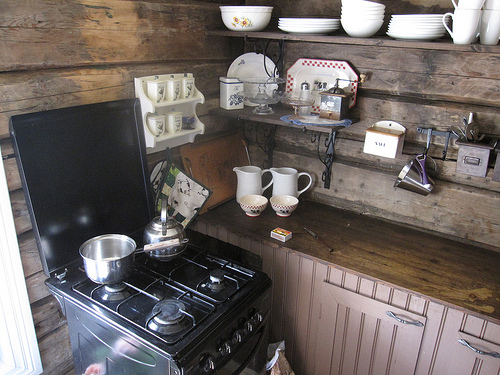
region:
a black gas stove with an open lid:
[6, 97, 278, 372]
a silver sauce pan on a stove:
[76, 233, 188, 286]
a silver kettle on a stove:
[140, 192, 191, 259]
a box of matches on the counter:
[268, 225, 293, 242]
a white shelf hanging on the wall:
[133, 70, 209, 156]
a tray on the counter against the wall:
[174, 131, 256, 214]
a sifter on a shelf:
[321, 73, 367, 122]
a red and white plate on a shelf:
[283, 58, 360, 116]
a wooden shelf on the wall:
[208, 102, 362, 190]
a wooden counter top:
[195, 192, 499, 357]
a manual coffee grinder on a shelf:
[320, 72, 368, 124]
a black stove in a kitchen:
[11, 100, 270, 372]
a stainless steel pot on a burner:
[81, 233, 138, 283]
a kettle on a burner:
[146, 192, 188, 256]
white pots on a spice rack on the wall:
[135, 74, 206, 151]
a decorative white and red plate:
[284, 56, 356, 109]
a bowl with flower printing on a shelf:
[218, 3, 273, 28]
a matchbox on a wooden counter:
[271, 225, 291, 245]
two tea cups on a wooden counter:
[240, 195, 301, 217]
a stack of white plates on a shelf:
[386, 13, 449, 41]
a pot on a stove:
[68, 237, 187, 287]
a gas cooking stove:
[57, 231, 262, 326]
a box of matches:
[254, 220, 294, 254]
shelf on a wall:
[224, 71, 373, 130]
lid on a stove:
[3, 89, 150, 274]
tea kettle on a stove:
[139, 196, 193, 266]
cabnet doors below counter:
[309, 274, 457, 371]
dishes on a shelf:
[209, 7, 499, 47]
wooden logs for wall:
[14, 2, 206, 104]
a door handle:
[383, 308, 437, 332]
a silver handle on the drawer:
[380, 303, 421, 330]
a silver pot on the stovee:
[80, 231, 135, 293]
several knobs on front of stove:
[197, 316, 246, 369]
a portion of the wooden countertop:
[381, 215, 492, 286]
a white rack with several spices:
[137, 77, 214, 141]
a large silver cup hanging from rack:
[398, 122, 436, 208]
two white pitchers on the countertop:
[235, 160, 314, 196]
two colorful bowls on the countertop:
[242, 192, 297, 219]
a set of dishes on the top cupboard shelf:
[203, 1, 490, 44]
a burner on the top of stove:
[128, 287, 202, 336]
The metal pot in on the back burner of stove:
[75, 230, 190, 285]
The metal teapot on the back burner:
[140, 193, 192, 260]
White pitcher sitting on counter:
[229, 162, 272, 217]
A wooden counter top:
[260, 218, 499, 280]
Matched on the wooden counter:
[266, 214, 298, 244]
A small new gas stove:
[31, 183, 276, 374]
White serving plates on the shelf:
[274, 0, 338, 45]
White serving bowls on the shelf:
[333, 0, 388, 40]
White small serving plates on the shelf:
[386, 3, 450, 44]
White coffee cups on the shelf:
[437, 0, 495, 45]